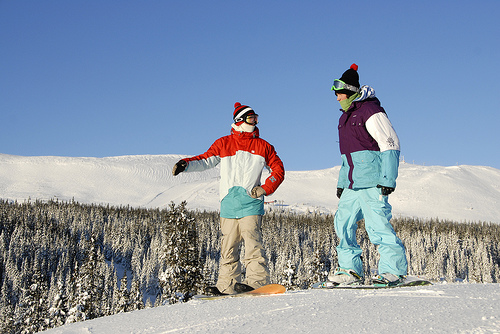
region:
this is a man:
[174, 102, 282, 292]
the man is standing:
[171, 102, 283, 301]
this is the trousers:
[219, 222, 258, 280]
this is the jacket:
[214, 137, 264, 185]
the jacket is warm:
[218, 135, 261, 185]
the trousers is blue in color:
[335, 199, 382, 257]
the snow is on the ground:
[293, 292, 359, 332]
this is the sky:
[35, 5, 161, 122]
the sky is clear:
[18, 3, 142, 118]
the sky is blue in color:
[24, 9, 151, 106]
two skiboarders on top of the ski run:
[171, 63, 444, 298]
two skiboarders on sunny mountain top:
[0, 0, 498, 332]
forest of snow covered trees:
[1, 197, 496, 327]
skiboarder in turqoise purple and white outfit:
[316, 62, 432, 287]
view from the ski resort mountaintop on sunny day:
[1, 10, 496, 330]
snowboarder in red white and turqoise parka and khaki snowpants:
[171, 102, 286, 292]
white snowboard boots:
[326, 270, 405, 285]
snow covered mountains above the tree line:
[4, 155, 498, 225]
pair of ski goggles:
[235, 113, 259, 124]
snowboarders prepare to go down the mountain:
[0, 5, 496, 332]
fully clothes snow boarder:
[163, 85, 291, 303]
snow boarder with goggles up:
[320, 53, 428, 319]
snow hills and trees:
[11, 141, 203, 308]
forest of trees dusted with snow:
[12, 196, 174, 299]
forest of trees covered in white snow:
[418, 210, 499, 275]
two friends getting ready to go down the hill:
[156, 48, 418, 319]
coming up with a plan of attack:
[163, 58, 453, 310]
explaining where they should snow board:
[152, 93, 292, 315]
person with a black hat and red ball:
[304, 36, 415, 296]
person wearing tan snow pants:
[160, 76, 293, 306]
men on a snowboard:
[154, 28, 497, 301]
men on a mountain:
[172, 68, 427, 325]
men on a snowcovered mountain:
[174, 40, 475, 285]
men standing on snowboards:
[147, 63, 464, 326]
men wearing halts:
[165, 51, 469, 307]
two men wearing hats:
[128, 63, 421, 278]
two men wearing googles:
[190, 68, 447, 279]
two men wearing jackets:
[192, 82, 470, 279]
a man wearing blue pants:
[309, 48, 439, 246]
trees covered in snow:
[17, 156, 245, 333]